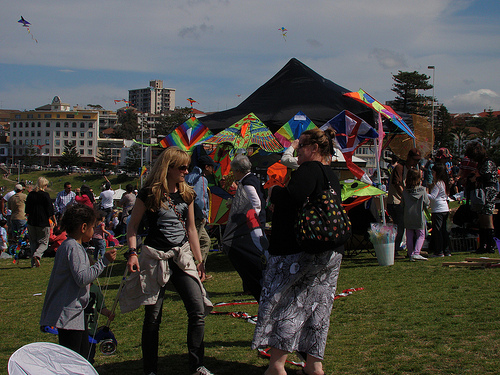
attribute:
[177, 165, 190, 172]
sunglasses — brown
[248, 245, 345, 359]
skirt — grey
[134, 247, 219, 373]
pants — woman's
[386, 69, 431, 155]
tree — tall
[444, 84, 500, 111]
cloud — small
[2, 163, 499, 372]
grass — green, patchy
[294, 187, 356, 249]
purse — multicolored, polka-dotted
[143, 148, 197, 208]
hair — blonde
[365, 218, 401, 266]
bucket — white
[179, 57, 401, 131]
tent — black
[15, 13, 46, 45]
kite — flying, green, red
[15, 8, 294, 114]
kites — colorful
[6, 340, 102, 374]
kite — white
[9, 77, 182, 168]
buildings — white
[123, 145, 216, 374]
woman — walking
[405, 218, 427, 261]
pants — purple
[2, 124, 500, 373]
people — standing, walking, enjoying, present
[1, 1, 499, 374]
area — big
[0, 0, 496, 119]
weather — enjoyable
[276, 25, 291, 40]
kite — rainbow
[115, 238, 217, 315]
jacket — wrapped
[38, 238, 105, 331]
shirt — grey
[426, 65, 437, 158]
lamp post — metal